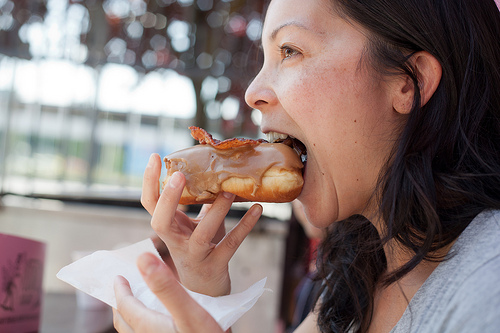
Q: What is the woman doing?
A: Eating.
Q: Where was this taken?
A: At a restaurant.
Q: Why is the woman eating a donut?
A: She is hungry.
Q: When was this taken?
A: During the day.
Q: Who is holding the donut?
A: The woman.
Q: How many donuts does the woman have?
A: One.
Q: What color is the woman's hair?
A: Dark brown.